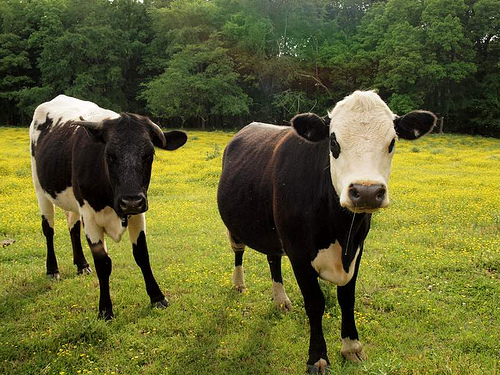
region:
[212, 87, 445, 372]
a black and white cow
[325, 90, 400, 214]
a cow with a white face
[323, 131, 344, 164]
a cow with a black eye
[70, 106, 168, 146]
horns on a cow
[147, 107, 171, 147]
a curved horn on a cow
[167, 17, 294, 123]
a wooded area behind the cows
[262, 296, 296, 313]
a white hoof on a cow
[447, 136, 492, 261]
yellow flowers in the grass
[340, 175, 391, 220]
the grays nose of a cow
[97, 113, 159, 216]
a cow with a black head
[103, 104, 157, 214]
A black head of a cow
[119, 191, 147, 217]
Black muzzle of a cow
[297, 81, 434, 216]
White and black head of a cow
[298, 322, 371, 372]
Legs of a cow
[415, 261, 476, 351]
Grass in the photo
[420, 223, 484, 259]
Yellow flowers in the photo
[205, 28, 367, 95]
Trees in the photo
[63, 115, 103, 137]
A horn in the photo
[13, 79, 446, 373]
Cows in the photo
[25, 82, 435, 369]
two cows standing a field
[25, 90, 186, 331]
a cow standing in a field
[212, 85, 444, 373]
a cow standing a field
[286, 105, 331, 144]
an ear of a cow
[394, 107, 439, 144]
an ear of a cow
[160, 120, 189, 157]
an ear of a cow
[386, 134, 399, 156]
an eye of a cow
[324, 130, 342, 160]
an eye of a cow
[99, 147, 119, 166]
an eye of a cow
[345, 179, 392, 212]
the nose of a cow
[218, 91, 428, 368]
black and white cow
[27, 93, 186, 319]
white and black cow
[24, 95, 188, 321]
cow standing on grass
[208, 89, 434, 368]
cow standing on field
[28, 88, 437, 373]
two cows on field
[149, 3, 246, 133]
evergreen tree on field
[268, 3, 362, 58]
tree with green leaves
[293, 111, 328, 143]
black ear on cow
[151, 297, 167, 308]
black hoof on cow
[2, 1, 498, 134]
trees next to field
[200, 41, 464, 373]
White and black cow in a field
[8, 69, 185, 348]
White and black cow in a field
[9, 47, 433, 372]
White and black cows in a field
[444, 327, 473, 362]
Patch of green grass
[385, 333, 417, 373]
Patch of green grass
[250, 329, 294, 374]
Patch of green grass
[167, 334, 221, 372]
Patch of green grass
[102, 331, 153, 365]
Patch of green grass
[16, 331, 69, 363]
Patch of green grass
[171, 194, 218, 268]
Patch of green grass